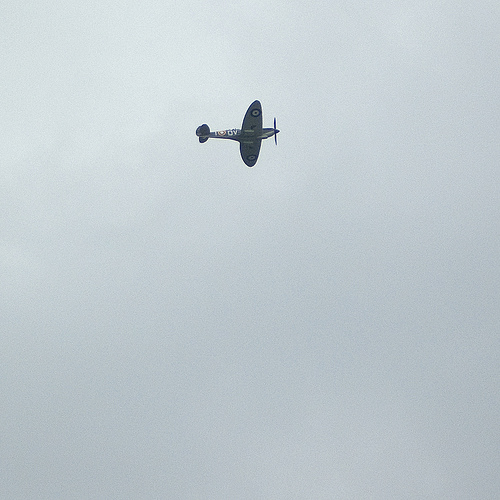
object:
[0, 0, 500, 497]
sky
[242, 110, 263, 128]
wing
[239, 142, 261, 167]
wing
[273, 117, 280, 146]
propellor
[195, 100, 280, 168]
plane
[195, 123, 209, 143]
tail wing